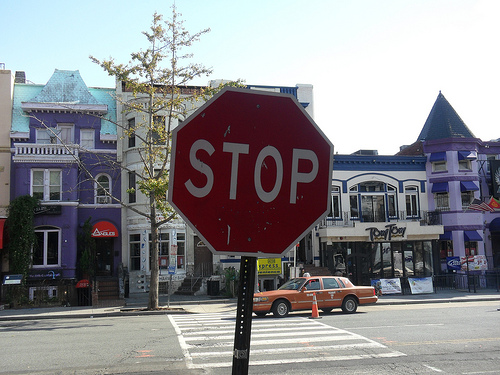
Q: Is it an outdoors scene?
A: Yes, it is outdoors.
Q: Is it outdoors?
A: Yes, it is outdoors.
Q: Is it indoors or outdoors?
A: It is outdoors.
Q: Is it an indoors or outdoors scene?
A: It is outdoors.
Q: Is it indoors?
A: No, it is outdoors.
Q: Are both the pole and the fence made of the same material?
A: Yes, both the pole and the fence are made of metal.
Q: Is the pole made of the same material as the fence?
A: Yes, both the pole and the fence are made of metal.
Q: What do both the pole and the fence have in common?
A: The material, both the pole and the fence are metallic.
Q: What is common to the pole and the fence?
A: The material, both the pole and the fence are metallic.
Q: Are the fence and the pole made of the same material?
A: Yes, both the fence and the pole are made of metal.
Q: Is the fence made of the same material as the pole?
A: Yes, both the fence and the pole are made of metal.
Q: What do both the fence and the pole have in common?
A: The material, both the fence and the pole are metallic.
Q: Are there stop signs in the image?
A: Yes, there is a stop sign.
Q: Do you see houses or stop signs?
A: Yes, there is a stop sign.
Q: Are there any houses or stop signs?
A: Yes, there is a stop sign.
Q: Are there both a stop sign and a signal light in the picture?
A: No, there is a stop sign but no traffic lights.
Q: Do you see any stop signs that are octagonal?
A: Yes, there is an octagonal stop sign.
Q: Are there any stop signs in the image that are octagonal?
A: Yes, there is a stop sign that is octagonal.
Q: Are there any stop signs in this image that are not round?
A: Yes, there is a octagonal stop sign.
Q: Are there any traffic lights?
A: No, there are no traffic lights.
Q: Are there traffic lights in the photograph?
A: No, there are no traffic lights.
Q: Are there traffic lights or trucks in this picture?
A: No, there are no traffic lights or trucks.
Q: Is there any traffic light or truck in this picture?
A: No, there are no traffic lights or trucks.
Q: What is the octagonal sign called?
A: The sign is a stop sign.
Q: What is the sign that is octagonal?
A: The sign is a stop sign.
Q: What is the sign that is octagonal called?
A: The sign is a stop sign.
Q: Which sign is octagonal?
A: The sign is a stop sign.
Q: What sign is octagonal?
A: The sign is a stop sign.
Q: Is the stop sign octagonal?
A: Yes, the stop sign is octagonal.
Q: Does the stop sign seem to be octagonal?
A: Yes, the stop sign is octagonal.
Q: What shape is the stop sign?
A: The stop sign is octagonal.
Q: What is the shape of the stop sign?
A: The stop sign is octagonal.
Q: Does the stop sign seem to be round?
A: No, the stop sign is octagonal.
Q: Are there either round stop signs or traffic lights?
A: No, there is a stop sign but it is octagonal.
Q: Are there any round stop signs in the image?
A: No, there is a stop sign but it is octagonal.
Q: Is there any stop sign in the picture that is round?
A: No, there is a stop sign but it is octagonal.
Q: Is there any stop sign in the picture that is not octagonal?
A: No, there is a stop sign but it is octagonal.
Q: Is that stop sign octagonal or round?
A: The stop sign is octagonal.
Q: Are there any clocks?
A: No, there are no clocks.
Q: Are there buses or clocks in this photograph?
A: No, there are no clocks or buses.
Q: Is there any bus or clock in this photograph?
A: No, there are no clocks or buses.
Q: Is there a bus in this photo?
A: No, there are no buses.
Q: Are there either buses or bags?
A: No, there are no buses or bags.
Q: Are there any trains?
A: No, there are no trains.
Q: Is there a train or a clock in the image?
A: No, there are no trains or clocks.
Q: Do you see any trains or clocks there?
A: No, there are no trains or clocks.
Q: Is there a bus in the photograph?
A: No, there are no buses.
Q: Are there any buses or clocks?
A: No, there are no buses or clocks.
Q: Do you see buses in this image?
A: No, there are no buses.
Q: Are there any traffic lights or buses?
A: No, there are no buses or traffic lights.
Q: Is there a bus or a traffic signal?
A: No, there are no buses or traffic lights.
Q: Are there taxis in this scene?
A: Yes, there is a taxi.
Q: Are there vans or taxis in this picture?
A: Yes, there is a taxi.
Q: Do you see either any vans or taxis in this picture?
A: Yes, there is a taxi.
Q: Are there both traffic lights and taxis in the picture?
A: No, there is a taxi but no traffic lights.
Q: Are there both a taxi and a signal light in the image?
A: No, there is a taxi but no traffic lights.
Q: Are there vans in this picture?
A: No, there are no vans.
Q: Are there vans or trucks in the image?
A: No, there are no vans or trucks.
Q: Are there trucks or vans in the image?
A: No, there are no vans or trucks.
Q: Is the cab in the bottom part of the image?
A: Yes, the cab is in the bottom of the image.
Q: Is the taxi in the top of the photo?
A: No, the taxi is in the bottom of the image.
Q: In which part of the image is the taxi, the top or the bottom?
A: The taxi is in the bottom of the image.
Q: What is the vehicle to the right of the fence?
A: The vehicle is a taxi.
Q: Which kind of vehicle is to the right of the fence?
A: The vehicle is a taxi.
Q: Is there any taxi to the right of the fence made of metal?
A: Yes, there is a taxi to the right of the fence.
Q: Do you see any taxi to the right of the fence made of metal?
A: Yes, there is a taxi to the right of the fence.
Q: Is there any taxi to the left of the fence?
A: No, the taxi is to the right of the fence.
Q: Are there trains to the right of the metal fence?
A: No, there is a taxi to the right of the fence.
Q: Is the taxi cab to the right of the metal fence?
A: Yes, the taxi cab is to the right of the fence.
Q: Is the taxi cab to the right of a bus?
A: No, the taxi cab is to the right of the fence.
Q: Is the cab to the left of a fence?
A: No, the cab is to the right of a fence.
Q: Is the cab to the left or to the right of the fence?
A: The cab is to the right of the fence.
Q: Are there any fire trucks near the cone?
A: No, there is a taxi near the cone.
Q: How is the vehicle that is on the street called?
A: The vehicle is a taxi.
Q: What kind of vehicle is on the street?
A: The vehicle is a taxi.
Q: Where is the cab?
A: The cab is on the street.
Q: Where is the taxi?
A: The cab is on the street.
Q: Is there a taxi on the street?
A: Yes, there is a taxi on the street.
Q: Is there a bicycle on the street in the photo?
A: No, there is a taxi on the street.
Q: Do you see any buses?
A: No, there are no buses.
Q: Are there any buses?
A: No, there are no buses.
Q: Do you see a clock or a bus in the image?
A: No, there are no clocks or buses.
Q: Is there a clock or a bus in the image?
A: No, there are no clocks or buses.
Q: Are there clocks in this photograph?
A: No, there are no clocks.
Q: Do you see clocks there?
A: No, there are no clocks.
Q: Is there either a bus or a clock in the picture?
A: No, there are no clocks or buses.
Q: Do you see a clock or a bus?
A: No, there are no clocks or buses.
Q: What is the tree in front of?
A: The tree is in front of the building.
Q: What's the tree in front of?
A: The tree is in front of the building.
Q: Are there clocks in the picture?
A: No, there are no clocks.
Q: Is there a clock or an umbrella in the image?
A: No, there are no clocks or umbrellas.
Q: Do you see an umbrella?
A: No, there are no umbrellas.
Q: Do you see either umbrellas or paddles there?
A: No, there are no umbrellas or paddles.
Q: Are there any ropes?
A: No, there are no ropes.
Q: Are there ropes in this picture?
A: No, there are no ropes.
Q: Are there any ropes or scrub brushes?
A: No, there are no ropes or scrub brushes.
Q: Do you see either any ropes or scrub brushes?
A: No, there are no ropes or scrub brushes.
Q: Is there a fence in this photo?
A: Yes, there is a fence.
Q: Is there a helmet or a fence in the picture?
A: Yes, there is a fence.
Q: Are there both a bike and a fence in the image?
A: No, there is a fence but no bikes.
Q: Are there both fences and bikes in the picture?
A: No, there is a fence but no bikes.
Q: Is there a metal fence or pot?
A: Yes, there is a metal fence.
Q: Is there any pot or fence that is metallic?
A: Yes, the fence is metallic.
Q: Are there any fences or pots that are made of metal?
A: Yes, the fence is made of metal.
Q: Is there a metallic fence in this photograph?
A: Yes, there is a metal fence.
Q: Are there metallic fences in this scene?
A: Yes, there is a metal fence.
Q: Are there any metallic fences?
A: Yes, there is a metal fence.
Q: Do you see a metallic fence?
A: Yes, there is a metal fence.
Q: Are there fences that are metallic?
A: Yes, there is a fence that is metallic.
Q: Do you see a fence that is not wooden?
A: Yes, there is a metallic fence.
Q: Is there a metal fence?
A: Yes, there is a fence that is made of metal.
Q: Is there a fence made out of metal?
A: Yes, there is a fence that is made of metal.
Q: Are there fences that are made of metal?
A: Yes, there is a fence that is made of metal.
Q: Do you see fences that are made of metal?
A: Yes, there is a fence that is made of metal.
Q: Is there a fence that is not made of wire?
A: Yes, there is a fence that is made of metal.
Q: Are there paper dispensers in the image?
A: No, there are no paper dispensers.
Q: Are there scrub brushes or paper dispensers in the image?
A: No, there are no paper dispensers or scrub brushes.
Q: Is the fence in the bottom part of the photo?
A: Yes, the fence is in the bottom of the image.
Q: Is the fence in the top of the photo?
A: No, the fence is in the bottom of the image.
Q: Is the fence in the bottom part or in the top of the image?
A: The fence is in the bottom of the image.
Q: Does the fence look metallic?
A: Yes, the fence is metallic.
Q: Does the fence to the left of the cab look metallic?
A: Yes, the fence is metallic.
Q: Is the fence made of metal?
A: Yes, the fence is made of metal.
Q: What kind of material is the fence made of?
A: The fence is made of metal.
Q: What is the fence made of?
A: The fence is made of metal.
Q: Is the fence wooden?
A: No, the fence is metallic.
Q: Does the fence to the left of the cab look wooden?
A: No, the fence is metallic.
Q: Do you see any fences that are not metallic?
A: No, there is a fence but it is metallic.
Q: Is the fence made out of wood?
A: No, the fence is made of metal.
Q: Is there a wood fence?
A: No, there is a fence but it is made of metal.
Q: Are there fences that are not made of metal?
A: No, there is a fence but it is made of metal.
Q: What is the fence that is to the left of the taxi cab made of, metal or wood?
A: The fence is made of metal.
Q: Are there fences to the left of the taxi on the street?
A: Yes, there is a fence to the left of the taxi cab.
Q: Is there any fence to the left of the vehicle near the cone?
A: Yes, there is a fence to the left of the taxi cab.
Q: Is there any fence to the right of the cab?
A: No, the fence is to the left of the cab.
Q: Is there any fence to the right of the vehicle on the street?
A: No, the fence is to the left of the cab.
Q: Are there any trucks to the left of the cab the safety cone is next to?
A: No, there is a fence to the left of the cab.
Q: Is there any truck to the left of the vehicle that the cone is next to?
A: No, there is a fence to the left of the cab.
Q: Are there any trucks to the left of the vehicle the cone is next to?
A: No, there is a fence to the left of the cab.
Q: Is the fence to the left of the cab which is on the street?
A: Yes, the fence is to the left of the taxi.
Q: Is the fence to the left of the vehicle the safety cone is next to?
A: Yes, the fence is to the left of the taxi.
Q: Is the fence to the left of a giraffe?
A: No, the fence is to the left of the taxi.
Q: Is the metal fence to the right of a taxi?
A: No, the fence is to the left of a taxi.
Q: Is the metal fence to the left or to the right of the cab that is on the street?
A: The fence is to the left of the cab.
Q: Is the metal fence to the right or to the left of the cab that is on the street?
A: The fence is to the left of the cab.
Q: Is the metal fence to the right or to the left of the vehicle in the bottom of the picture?
A: The fence is to the left of the cab.